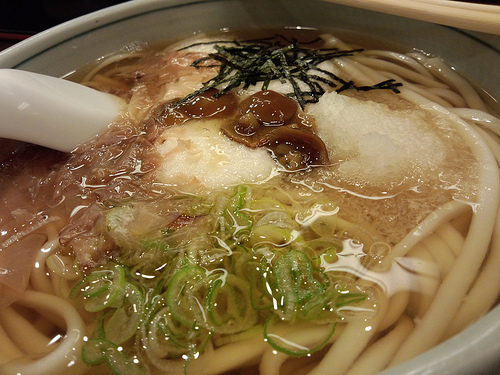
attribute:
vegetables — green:
[65, 184, 371, 374]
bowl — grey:
[424, 323, 499, 369]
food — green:
[75, 197, 370, 372]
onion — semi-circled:
[1, 288, 88, 372]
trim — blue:
[63, 12, 125, 50]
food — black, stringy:
[176, 28, 425, 116]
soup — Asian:
[0, 15, 499, 373]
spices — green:
[185, 26, 402, 102]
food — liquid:
[2, 26, 497, 373]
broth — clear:
[14, 96, 495, 349]